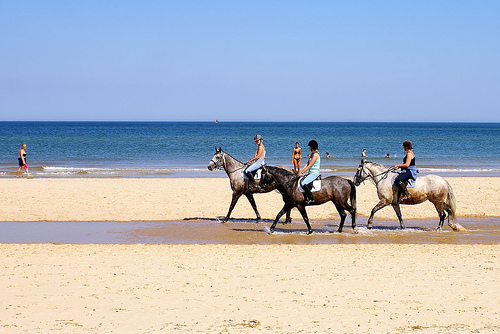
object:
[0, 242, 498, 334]
sand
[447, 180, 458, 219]
long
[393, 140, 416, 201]
woman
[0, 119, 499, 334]
scene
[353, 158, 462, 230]
horse